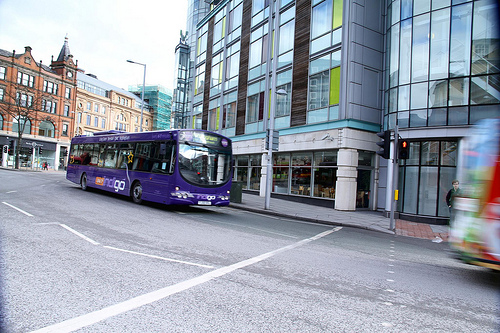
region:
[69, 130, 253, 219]
a purple commercial bus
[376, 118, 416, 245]
a street light in background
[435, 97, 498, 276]
a bus moving fast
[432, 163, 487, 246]
a person waiting for the bus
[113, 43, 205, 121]
a light for the night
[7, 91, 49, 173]
an old brown tree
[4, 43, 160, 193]
a brown big building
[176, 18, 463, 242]
a big shopping complex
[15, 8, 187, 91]
a clear bright sky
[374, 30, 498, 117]
clear reflective windows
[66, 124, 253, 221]
purple commercial bus on road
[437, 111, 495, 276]
commercial bust moving fast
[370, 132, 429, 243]
street lights on road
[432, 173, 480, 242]
man waiting to get on the bus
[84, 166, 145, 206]
advertisements on the bus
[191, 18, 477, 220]
huge shopping complex across road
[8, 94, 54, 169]
leafless tree in background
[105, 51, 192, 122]
grey street lights for the night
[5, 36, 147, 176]
huge brown building in background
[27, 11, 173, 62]
clear bright sky in bacground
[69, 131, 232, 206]
purple bus near the curb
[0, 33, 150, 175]
red buiding in the background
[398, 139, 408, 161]
pedestrian sign with orange light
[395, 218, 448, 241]
section of sidewalk with red bricks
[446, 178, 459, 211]
man wearing a black jacket with his hands in this pockets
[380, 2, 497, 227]
curved looking glass building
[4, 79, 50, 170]
bare tree in front of the red building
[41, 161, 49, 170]
person in black sitting on a red bench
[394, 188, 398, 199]
yellow sign on sign pole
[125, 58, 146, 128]
streetlight with a tall, bent pole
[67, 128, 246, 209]
Purple city bus.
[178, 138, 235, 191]
Front window of purple bus.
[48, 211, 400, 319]
Marking on the street.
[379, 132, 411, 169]
Street traffic light.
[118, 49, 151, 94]
City street light.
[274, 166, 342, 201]
Business window with tables and chairs inside.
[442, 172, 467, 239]
Person standing on sidewalk near the street.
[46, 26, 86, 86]
Tower with round clock.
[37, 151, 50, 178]
People walking downtown on sidewalk.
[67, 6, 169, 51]
Pale blue sky.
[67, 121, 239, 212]
a blue bus on a street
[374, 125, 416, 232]
a streetlight on the side of the road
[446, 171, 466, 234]
a person standing on the sidewalk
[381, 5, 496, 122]
glass windows on a building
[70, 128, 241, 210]
a dark blue bus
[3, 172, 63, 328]
part of a paved road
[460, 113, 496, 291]
back of a driving bus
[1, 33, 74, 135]
a red brick building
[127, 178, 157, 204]
black wheel of a bus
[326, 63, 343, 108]
a yellow green window